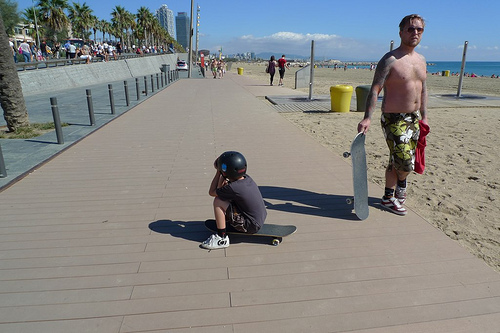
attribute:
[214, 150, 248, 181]
helmet — black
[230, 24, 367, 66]
cloud — large, white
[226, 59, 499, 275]
sand — brown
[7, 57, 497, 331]
boardwalk — long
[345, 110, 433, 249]
skateboard — black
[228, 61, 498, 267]
beach — sandy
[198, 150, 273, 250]
boy — young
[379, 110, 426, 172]
shorts — black, white, yellow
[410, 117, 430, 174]
shirt — red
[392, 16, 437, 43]
sunglasses — dark brown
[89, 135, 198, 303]
walk way — wooden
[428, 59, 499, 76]
ocean — small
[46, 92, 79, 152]
pole — short, gray